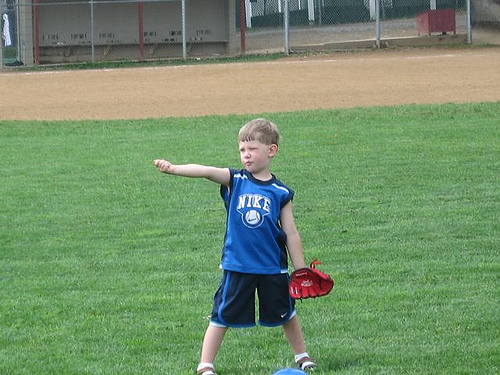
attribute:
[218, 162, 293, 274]
shirt — blue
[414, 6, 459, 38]
bin — red, large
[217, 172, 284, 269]
jersey — blue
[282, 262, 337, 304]
glove — red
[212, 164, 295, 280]
shirt — blue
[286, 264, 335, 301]
mitt — red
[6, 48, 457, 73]
line — white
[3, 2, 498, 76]
fence — chain link, metal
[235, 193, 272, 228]
logo — Nike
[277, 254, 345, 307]
baseball mitt — red